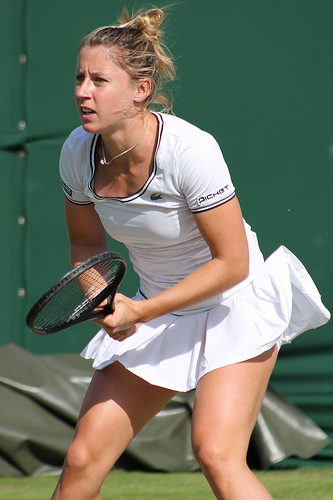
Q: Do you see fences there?
A: No, there are no fences.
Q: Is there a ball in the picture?
A: No, there are no balls.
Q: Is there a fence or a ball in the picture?
A: No, there are no balls or fences.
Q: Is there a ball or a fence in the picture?
A: No, there are no balls or fences.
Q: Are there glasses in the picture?
A: No, there are no glasses.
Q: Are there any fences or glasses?
A: No, there are no glasses or fences.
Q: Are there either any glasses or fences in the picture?
A: No, there are no glasses or fences.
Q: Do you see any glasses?
A: No, there are no glasses.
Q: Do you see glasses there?
A: No, there are no glasses.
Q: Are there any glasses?
A: No, there are no glasses.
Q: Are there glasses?
A: No, there are no glasses.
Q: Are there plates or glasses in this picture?
A: No, there are no glasses or plates.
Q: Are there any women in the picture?
A: Yes, there is a woman.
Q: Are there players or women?
A: Yes, there is a woman.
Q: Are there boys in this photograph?
A: No, there are no boys.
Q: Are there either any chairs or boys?
A: No, there are no boys or chairs.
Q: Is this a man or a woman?
A: This is a woman.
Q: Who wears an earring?
A: The woman wears an earring.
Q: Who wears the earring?
A: The woman wears an earring.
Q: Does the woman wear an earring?
A: Yes, the woman wears an earring.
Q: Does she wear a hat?
A: No, the woman wears an earring.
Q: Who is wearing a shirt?
A: The woman is wearing a shirt.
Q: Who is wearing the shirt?
A: The woman is wearing a shirt.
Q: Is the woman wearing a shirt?
A: Yes, the woman is wearing a shirt.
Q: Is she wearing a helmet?
A: No, the woman is wearing a shirt.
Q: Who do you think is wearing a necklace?
A: The woman is wearing a necklace.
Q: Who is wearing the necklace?
A: The woman is wearing a necklace.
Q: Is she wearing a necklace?
A: Yes, the woman is wearing a necklace.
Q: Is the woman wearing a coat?
A: No, the woman is wearing a necklace.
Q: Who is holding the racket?
A: The woman is holding the racket.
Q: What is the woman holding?
A: The woman is holding the tennis racket.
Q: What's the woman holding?
A: The woman is holding the tennis racket.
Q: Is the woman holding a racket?
A: Yes, the woman is holding a racket.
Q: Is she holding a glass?
A: No, the woman is holding a racket.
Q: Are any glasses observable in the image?
A: No, there are no glasses.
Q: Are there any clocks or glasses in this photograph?
A: No, there are no glasses or clocks.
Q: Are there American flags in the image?
A: No, there are no American flags.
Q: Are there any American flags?
A: No, there are no American flags.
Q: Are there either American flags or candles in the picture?
A: No, there are no American flags or candles.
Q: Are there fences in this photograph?
A: No, there are no fences.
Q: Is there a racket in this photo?
A: Yes, there is a racket.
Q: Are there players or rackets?
A: Yes, there is a racket.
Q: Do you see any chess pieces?
A: No, there are no chess pieces.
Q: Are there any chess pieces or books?
A: No, there are no chess pieces or books.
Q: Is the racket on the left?
A: Yes, the racket is on the left of the image.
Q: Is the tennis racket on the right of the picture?
A: No, the tennis racket is on the left of the image.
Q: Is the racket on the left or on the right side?
A: The racket is on the left of the image.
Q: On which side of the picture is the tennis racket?
A: The tennis racket is on the left of the image.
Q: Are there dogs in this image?
A: No, there are no dogs.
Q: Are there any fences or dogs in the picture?
A: No, there are no dogs or fences.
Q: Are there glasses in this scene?
A: No, there are no glasses.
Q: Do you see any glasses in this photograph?
A: No, there are no glasses.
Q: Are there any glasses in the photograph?
A: No, there are no glasses.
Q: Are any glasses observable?
A: No, there are no glasses.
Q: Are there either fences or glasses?
A: No, there are no glasses or fences.